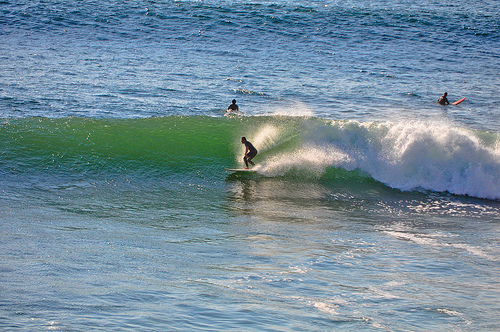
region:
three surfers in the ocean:
[213, 56, 479, 203]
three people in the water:
[191, 27, 480, 211]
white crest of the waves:
[299, 123, 468, 210]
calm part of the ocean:
[153, 230, 326, 316]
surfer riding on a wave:
[224, 130, 264, 185]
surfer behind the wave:
[219, 87, 253, 134]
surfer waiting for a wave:
[423, 71, 471, 116]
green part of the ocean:
[116, 121, 187, 162]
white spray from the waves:
[250, 116, 290, 167]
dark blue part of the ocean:
[221, 9, 268, 37]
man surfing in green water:
[226, 135, 265, 175]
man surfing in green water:
[215, 77, 256, 128]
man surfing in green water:
[429, 68, 456, 105]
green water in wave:
[83, 119, 180, 160]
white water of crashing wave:
[401, 140, 462, 196]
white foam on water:
[303, 272, 363, 319]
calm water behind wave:
[155, 23, 379, 93]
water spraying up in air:
[266, 81, 327, 118]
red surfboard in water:
[453, 90, 463, 117]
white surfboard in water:
[231, 165, 265, 179]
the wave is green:
[25, 104, 497, 201]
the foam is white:
[287, 114, 496, 204]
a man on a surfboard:
[221, 129, 261, 176]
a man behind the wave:
[225, 96, 240, 120]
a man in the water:
[430, 87, 449, 105]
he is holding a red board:
[444, 95, 474, 113]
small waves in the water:
[227, 216, 482, 330]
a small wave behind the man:
[223, 74, 267, 99]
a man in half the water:
[221, 94, 241, 116]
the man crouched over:
[235, 129, 262, 171]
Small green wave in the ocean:
[7, 100, 499, 202]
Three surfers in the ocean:
[202, 71, 473, 184]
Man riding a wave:
[219, 128, 275, 185]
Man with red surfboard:
[429, 89, 471, 111]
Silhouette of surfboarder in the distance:
[219, 88, 253, 117]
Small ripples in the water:
[18, 186, 493, 328]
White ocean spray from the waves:
[211, 99, 498, 207]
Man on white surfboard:
[219, 129, 267, 184]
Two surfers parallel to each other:
[224, 93, 283, 189]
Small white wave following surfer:
[233, 108, 499, 222]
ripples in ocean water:
[246, 17, 353, 62]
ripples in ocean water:
[143, 19, 199, 43]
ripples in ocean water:
[22, 15, 86, 57]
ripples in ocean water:
[63, 160, 154, 240]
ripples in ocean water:
[299, 228, 367, 293]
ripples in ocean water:
[198, 262, 255, 316]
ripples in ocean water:
[57, 265, 137, 310]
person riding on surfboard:
[420, 73, 479, 115]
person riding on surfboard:
[223, 115, 274, 189]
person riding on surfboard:
[217, 86, 247, 127]